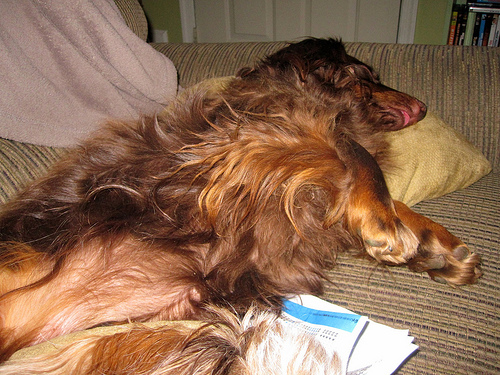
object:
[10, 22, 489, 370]
dog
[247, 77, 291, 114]
hair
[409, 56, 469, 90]
couch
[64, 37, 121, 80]
blanket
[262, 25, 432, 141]
head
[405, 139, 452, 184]
pillow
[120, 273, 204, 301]
belly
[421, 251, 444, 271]
paw pads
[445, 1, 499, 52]
bookshelf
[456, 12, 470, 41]
books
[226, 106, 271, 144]
patch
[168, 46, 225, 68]
sofa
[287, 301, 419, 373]
paper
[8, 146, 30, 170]
stripes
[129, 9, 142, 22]
fabric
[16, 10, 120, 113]
towel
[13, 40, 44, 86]
cloth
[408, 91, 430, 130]
snout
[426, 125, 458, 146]
cushion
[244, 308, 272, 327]
sheaf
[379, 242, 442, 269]
paws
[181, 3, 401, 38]
door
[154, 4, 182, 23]
wall